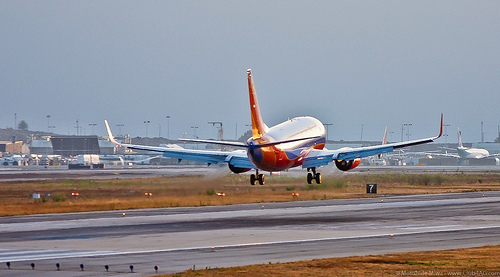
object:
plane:
[100, 66, 448, 187]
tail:
[244, 67, 271, 141]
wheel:
[258, 173, 267, 186]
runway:
[0, 191, 499, 277]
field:
[0, 169, 500, 219]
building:
[29, 136, 117, 157]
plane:
[423, 126, 500, 166]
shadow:
[0, 212, 459, 244]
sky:
[2, 0, 499, 145]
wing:
[299, 110, 447, 170]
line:
[2, 261, 168, 277]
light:
[152, 263, 159, 274]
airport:
[1, 110, 500, 275]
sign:
[366, 182, 378, 194]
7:
[366, 184, 377, 194]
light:
[144, 191, 153, 199]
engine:
[333, 157, 362, 172]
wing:
[102, 118, 260, 172]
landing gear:
[304, 166, 325, 185]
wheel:
[248, 173, 256, 186]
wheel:
[314, 172, 322, 185]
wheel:
[305, 172, 314, 184]